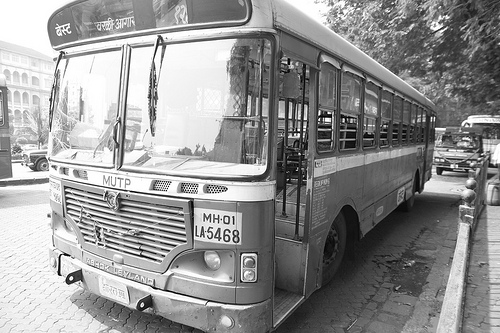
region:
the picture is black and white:
[1, 0, 497, 330]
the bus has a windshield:
[34, 30, 278, 180]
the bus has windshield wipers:
[45, 34, 172, 152]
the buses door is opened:
[272, 42, 321, 327]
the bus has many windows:
[316, 50, 439, 153]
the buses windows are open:
[312, 50, 439, 153]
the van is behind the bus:
[433, 119, 481, 184]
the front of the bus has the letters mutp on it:
[99, 172, 133, 194]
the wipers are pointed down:
[46, 35, 171, 145]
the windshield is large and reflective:
[40, 31, 283, 191]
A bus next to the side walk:
[39, 8, 452, 330]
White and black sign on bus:
[186, 203, 250, 257]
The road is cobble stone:
[3, 221, 141, 315]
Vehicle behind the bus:
[428, 114, 493, 181]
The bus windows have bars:
[271, 47, 443, 182]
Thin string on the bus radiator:
[65, 181, 192, 249]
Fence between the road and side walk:
[454, 141, 491, 237]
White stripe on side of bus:
[306, 140, 437, 174]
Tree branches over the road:
[322, 16, 497, 144]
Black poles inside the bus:
[279, 65, 314, 239]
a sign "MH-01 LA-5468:
[188, 207, 245, 247]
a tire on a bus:
[322, 206, 344, 296]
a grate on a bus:
[58, 175, 194, 280]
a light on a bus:
[200, 248, 222, 270]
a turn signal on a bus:
[240, 255, 261, 284]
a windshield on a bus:
[126, 40, 268, 181]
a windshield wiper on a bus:
[143, 38, 165, 133]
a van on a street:
[437, 127, 484, 179]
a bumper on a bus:
[48, 244, 278, 331]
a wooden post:
[460, 149, 485, 233]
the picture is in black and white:
[4, 0, 499, 332]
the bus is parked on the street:
[36, 1, 435, 328]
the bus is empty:
[41, 0, 435, 330]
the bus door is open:
[274, 49, 318, 321]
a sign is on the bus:
[188, 206, 245, 249]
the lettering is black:
[195, 208, 241, 244]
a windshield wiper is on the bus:
[146, 35, 168, 137]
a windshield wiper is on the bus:
[47, 51, 64, 123]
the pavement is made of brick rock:
[1, 174, 491, 331]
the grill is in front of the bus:
[62, 177, 196, 284]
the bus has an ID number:
[187, 204, 251, 250]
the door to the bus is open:
[262, 48, 309, 319]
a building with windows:
[1, 45, 52, 149]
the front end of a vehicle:
[19, 139, 53, 176]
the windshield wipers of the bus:
[36, 37, 171, 138]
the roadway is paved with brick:
[0, 227, 44, 332]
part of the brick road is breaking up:
[373, 228, 443, 320]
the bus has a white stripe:
[313, 135, 441, 176]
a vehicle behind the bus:
[433, 125, 480, 177]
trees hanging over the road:
[326, 2, 497, 97]